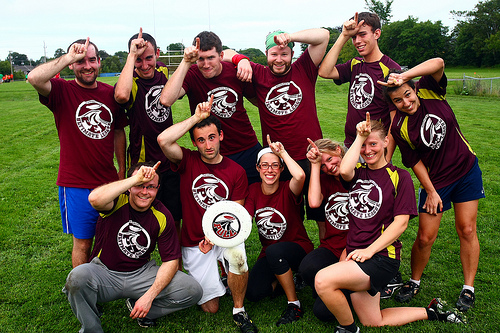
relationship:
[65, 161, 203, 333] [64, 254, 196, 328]
man with pants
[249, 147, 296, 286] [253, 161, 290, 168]
woman with glasses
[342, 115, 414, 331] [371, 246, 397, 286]
girl has on shorts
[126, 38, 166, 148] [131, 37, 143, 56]
man with hand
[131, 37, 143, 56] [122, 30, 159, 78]
hand on head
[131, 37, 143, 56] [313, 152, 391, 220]
hand making sign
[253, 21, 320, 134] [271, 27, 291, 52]
man with hand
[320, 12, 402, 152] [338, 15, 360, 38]
man with hand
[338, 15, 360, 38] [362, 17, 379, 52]
hand on head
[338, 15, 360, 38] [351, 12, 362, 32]
hand making sign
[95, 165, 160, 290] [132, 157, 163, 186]
man with hand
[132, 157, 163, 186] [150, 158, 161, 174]
hand making sign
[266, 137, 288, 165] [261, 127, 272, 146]
hand making sign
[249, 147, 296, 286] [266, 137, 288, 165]
woman with hand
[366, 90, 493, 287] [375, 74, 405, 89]
woman with hand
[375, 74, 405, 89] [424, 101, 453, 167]
hand making sign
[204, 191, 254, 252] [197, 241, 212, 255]
frisbee in hand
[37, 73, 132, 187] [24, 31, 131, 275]
shirt on man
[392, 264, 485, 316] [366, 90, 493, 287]
tennis shoes on woman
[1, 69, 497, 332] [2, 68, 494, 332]
grass on ground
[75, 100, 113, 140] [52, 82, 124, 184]
logo on shirt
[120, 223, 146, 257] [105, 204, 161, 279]
logo on t-shirt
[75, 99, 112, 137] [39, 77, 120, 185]
logo on shirt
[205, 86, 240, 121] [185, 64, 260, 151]
logo on t-shirt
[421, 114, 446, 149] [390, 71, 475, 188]
logo on shirt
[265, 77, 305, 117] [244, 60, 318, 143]
logo on shirt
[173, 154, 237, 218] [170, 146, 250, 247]
logo on shirt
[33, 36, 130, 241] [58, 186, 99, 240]
man wearing blue shorts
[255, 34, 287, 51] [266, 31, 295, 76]
green scarf on head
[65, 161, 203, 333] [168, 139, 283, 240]
man has on shirt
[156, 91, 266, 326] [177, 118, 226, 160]
head of man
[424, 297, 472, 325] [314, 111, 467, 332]
shoe of girl